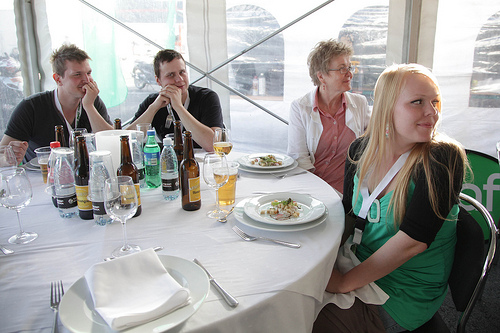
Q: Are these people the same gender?
A: No, they are both male and female.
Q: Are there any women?
A: Yes, there is a woman.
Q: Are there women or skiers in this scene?
A: Yes, there is a woman.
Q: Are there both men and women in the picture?
A: Yes, there are both a woman and a man.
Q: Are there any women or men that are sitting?
A: Yes, the woman is sitting.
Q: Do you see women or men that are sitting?
A: Yes, the woman is sitting.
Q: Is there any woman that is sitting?
A: Yes, there is a woman that is sitting.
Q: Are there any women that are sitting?
A: Yes, there is a woman that is sitting.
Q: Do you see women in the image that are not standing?
A: Yes, there is a woman that is sitting .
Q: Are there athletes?
A: No, there are no athletes.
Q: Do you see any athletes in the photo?
A: No, there are no athletes.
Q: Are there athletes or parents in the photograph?
A: No, there are no athletes or parents.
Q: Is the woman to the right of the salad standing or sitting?
A: The woman is sitting.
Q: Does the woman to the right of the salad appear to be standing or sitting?
A: The woman is sitting.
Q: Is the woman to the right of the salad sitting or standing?
A: The woman is sitting.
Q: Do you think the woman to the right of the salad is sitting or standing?
A: The woman is sitting.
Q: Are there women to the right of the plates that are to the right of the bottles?
A: Yes, there is a woman to the right of the plates.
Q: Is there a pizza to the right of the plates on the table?
A: No, there is a woman to the right of the plates.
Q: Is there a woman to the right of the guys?
A: Yes, there is a woman to the right of the guys.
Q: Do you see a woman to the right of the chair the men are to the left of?
A: Yes, there is a woman to the right of the chair.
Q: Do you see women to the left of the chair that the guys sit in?
A: No, the woman is to the right of the chair.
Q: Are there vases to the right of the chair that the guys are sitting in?
A: No, there is a woman to the right of the chair.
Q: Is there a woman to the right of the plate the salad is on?
A: Yes, there is a woman to the right of the plate.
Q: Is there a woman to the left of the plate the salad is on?
A: No, the woman is to the right of the plate.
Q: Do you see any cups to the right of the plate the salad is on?
A: No, there is a woman to the right of the plate.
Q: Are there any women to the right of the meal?
A: Yes, there is a woman to the right of the meal.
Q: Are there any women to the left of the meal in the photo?
A: No, the woman is to the right of the meal.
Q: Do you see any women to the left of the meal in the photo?
A: No, the woman is to the right of the meal.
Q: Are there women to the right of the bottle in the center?
A: Yes, there is a woman to the right of the bottle.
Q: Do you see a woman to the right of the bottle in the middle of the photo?
A: Yes, there is a woman to the right of the bottle.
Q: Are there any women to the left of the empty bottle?
A: No, the woman is to the right of the bottle.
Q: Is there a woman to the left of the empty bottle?
A: No, the woman is to the right of the bottle.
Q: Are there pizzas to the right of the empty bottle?
A: No, there is a woman to the right of the bottle.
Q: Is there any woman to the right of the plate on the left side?
A: Yes, there is a woman to the right of the plate.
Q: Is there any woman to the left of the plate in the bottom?
A: No, the woman is to the right of the plate.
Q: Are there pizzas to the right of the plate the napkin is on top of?
A: No, there is a woman to the right of the plate.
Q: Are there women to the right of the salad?
A: Yes, there is a woman to the right of the salad.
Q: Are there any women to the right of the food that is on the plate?
A: Yes, there is a woman to the right of the salad.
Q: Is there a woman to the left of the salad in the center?
A: No, the woman is to the right of the salad.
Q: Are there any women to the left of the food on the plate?
A: No, the woman is to the right of the salad.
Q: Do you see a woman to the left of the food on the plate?
A: No, the woman is to the right of the salad.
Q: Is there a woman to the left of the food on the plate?
A: No, the woman is to the right of the salad.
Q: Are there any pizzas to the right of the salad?
A: No, there is a woman to the right of the salad.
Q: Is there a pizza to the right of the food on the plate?
A: No, there is a woman to the right of the salad.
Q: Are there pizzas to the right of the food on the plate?
A: No, there is a woman to the right of the salad.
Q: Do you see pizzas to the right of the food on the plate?
A: No, there is a woman to the right of the salad.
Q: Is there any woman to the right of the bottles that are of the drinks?
A: Yes, there is a woman to the right of the bottles.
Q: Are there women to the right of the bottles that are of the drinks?
A: Yes, there is a woman to the right of the bottles.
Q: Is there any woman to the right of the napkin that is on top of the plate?
A: Yes, there is a woman to the right of the napkin.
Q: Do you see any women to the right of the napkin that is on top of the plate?
A: Yes, there is a woman to the right of the napkin.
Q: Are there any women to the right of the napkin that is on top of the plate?
A: Yes, there is a woman to the right of the napkin.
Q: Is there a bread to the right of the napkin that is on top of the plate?
A: No, there is a woman to the right of the napkin.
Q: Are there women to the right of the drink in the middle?
A: Yes, there is a woman to the right of the drink.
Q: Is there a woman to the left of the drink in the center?
A: No, the woman is to the right of the drink.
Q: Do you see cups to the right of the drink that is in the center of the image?
A: No, there is a woman to the right of the drink.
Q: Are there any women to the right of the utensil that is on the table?
A: Yes, there is a woman to the right of the fork.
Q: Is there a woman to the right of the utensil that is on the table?
A: Yes, there is a woman to the right of the fork.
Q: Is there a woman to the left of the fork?
A: No, the woman is to the right of the fork.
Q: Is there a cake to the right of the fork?
A: No, there is a woman to the right of the fork.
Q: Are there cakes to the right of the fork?
A: No, there is a woman to the right of the fork.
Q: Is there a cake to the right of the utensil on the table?
A: No, there is a woman to the right of the fork.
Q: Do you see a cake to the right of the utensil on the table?
A: No, there is a woman to the right of the fork.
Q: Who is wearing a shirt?
A: The woman is wearing a shirt.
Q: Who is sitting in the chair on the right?
A: The woman is sitting in the chair.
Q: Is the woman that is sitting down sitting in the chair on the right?
A: Yes, the woman is sitting in the chair.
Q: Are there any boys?
A: No, there are no boys.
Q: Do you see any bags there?
A: No, there are no bags.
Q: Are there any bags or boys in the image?
A: No, there are no bags or boys.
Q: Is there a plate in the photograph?
A: Yes, there is a plate.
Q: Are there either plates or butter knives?
A: Yes, there is a plate.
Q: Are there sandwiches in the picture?
A: No, there are no sandwiches.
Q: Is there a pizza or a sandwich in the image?
A: No, there are no sandwiches or pizzas.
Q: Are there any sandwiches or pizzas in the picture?
A: No, there are no sandwiches or pizzas.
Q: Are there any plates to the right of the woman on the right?
A: No, the plate is to the left of the woman.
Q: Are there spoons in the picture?
A: No, there are no spoons.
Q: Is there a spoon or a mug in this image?
A: No, there are no spoons or mugs.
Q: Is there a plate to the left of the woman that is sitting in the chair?
A: Yes, there are plates to the left of the woman.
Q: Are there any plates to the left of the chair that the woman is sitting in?
A: Yes, there are plates to the left of the chair.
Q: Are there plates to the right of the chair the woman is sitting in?
A: No, the plates are to the left of the chair.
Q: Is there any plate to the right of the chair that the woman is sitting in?
A: No, the plates are to the left of the chair.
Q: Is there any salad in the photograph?
A: Yes, there is salad.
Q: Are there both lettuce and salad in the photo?
A: No, there is salad but no lettuce.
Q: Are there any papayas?
A: No, there are no papayas.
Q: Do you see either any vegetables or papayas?
A: No, there are no papayas or vegetables.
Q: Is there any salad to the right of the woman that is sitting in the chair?
A: No, the salad is to the left of the woman.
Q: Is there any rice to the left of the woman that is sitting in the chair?
A: No, there is salad to the left of the woman.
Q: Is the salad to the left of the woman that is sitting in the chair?
A: Yes, the salad is to the left of the woman.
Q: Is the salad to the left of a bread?
A: No, the salad is to the left of the woman.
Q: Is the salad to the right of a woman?
A: No, the salad is to the left of a woman.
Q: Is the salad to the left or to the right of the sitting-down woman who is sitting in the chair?
A: The salad is to the left of the woman.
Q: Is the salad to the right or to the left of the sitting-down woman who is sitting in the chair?
A: The salad is to the left of the woman.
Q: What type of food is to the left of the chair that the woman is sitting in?
A: The food is salad.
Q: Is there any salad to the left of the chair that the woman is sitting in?
A: Yes, there is salad to the left of the chair.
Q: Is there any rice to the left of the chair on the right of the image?
A: No, there is salad to the left of the chair.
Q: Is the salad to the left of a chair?
A: Yes, the salad is to the left of a chair.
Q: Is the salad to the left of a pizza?
A: No, the salad is to the left of a chair.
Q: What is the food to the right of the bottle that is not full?
A: The food is salad.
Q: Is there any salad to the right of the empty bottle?
A: Yes, there is salad to the right of the bottle.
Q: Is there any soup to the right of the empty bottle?
A: No, there is salad to the right of the bottle.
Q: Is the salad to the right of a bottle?
A: Yes, the salad is to the right of a bottle.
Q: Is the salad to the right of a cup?
A: No, the salad is to the right of a bottle.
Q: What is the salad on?
A: The salad is on the plate.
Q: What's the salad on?
A: The salad is on the plate.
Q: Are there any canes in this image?
A: No, there are no canes.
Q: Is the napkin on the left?
A: Yes, the napkin is on the left of the image.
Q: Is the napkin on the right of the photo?
A: No, the napkin is on the left of the image.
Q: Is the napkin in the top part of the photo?
A: No, the napkin is in the bottom of the image.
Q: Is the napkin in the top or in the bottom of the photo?
A: The napkin is in the bottom of the image.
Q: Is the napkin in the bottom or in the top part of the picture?
A: The napkin is in the bottom of the image.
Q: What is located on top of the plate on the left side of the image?
A: The napkin is on top of the plate.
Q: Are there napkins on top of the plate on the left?
A: Yes, there is a napkin on top of the plate.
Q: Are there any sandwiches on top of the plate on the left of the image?
A: No, there is a napkin on top of the plate.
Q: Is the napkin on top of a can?
A: No, the napkin is on top of a plate.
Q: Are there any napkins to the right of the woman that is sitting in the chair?
A: No, the napkin is to the left of the woman.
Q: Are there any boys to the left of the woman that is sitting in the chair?
A: No, there is a napkin to the left of the woman.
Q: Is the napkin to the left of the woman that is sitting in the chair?
A: Yes, the napkin is to the left of the woman.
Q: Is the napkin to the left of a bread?
A: No, the napkin is to the left of the woman.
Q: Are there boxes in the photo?
A: No, there are no boxes.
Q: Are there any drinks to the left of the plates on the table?
A: Yes, there are drinks to the left of the plates.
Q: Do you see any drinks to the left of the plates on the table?
A: Yes, there are drinks to the left of the plates.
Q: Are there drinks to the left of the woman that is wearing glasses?
A: Yes, there are drinks to the left of the woman.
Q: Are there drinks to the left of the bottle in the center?
A: Yes, there are drinks to the left of the bottle.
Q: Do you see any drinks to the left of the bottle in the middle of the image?
A: Yes, there are drinks to the left of the bottle.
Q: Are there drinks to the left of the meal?
A: Yes, there are drinks to the left of the meal.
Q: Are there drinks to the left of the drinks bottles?
A: Yes, there are drinks to the left of the bottles.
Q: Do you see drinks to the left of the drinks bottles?
A: Yes, there are drinks to the left of the bottles.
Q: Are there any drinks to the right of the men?
A: Yes, there are drinks to the right of the men.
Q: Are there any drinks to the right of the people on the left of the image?
A: Yes, there are drinks to the right of the men.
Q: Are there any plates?
A: Yes, there is a plate.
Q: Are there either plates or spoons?
A: Yes, there is a plate.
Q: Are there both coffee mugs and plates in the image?
A: No, there is a plate but no coffee mugs.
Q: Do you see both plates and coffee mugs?
A: No, there is a plate but no coffee mugs.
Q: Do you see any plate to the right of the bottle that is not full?
A: Yes, there is a plate to the right of the bottle.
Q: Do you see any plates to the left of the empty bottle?
A: No, the plate is to the right of the bottle.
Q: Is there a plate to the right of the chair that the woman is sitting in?
A: No, the plate is to the left of the chair.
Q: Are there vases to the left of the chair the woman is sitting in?
A: No, there is a plate to the left of the chair.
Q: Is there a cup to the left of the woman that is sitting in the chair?
A: No, there is a plate to the left of the woman.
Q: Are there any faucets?
A: No, there are no faucets.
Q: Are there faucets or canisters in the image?
A: No, there are no faucets or canisters.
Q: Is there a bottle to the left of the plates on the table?
A: Yes, there are bottles to the left of the plates.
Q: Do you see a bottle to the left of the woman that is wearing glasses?
A: Yes, there are bottles to the left of the woman.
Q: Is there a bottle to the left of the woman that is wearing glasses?
A: Yes, there are bottles to the left of the woman.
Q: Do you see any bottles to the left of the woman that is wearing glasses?
A: Yes, there are bottles to the left of the woman.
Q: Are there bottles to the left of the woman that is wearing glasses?
A: Yes, there are bottles to the left of the woman.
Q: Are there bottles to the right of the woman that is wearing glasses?
A: No, the bottles are to the left of the woman.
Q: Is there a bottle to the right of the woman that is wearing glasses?
A: No, the bottles are to the left of the woman.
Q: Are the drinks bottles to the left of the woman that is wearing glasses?
A: Yes, the bottles are to the left of the woman.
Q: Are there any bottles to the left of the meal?
A: Yes, there are bottles to the left of the meal.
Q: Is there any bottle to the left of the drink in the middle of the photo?
A: Yes, there are bottles to the left of the drink.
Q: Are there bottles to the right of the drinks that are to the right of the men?
A: Yes, there are bottles to the right of the drinks.